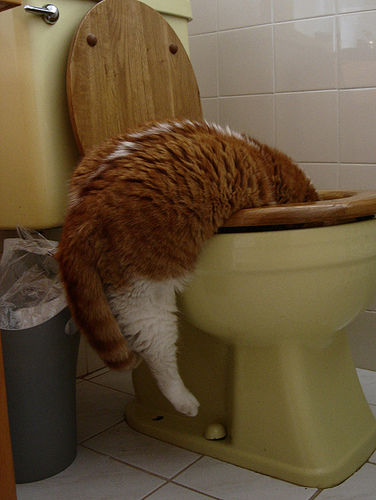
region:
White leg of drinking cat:
[123, 291, 203, 420]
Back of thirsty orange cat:
[153, 151, 234, 191]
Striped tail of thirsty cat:
[58, 242, 143, 387]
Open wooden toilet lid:
[61, 0, 212, 118]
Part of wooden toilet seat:
[261, 203, 330, 234]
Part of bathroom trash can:
[1, 238, 68, 414]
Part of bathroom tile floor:
[103, 451, 173, 492]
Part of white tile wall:
[234, 17, 323, 79]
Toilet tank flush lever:
[21, 1, 60, 26]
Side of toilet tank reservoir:
[5, 43, 50, 145]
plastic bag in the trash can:
[6, 236, 66, 333]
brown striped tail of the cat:
[62, 232, 143, 388]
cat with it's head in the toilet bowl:
[70, 140, 340, 377]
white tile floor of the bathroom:
[87, 435, 179, 496]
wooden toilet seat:
[270, 196, 373, 229]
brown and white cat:
[78, 150, 336, 420]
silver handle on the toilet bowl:
[21, 3, 67, 39]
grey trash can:
[6, 337, 87, 490]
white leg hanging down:
[102, 262, 212, 449]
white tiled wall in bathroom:
[219, 13, 358, 130]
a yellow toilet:
[1, 3, 368, 486]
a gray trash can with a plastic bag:
[3, 244, 79, 484]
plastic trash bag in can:
[0, 234, 69, 328]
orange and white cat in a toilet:
[66, 122, 320, 421]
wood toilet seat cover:
[70, 2, 202, 156]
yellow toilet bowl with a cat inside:
[64, 127, 372, 485]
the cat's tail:
[59, 211, 134, 369]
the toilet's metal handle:
[23, 1, 59, 23]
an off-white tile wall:
[197, 4, 373, 370]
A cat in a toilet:
[55, 6, 374, 487]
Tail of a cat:
[50, 228, 143, 376]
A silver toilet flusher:
[21, 0, 63, 30]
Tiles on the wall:
[187, 1, 372, 371]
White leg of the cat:
[140, 333, 203, 421]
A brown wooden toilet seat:
[60, 1, 372, 233]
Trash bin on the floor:
[1, 231, 101, 487]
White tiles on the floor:
[14, 362, 373, 497]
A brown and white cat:
[53, 110, 321, 422]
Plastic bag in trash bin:
[0, 228, 89, 487]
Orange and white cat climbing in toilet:
[51, 118, 320, 415]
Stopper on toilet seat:
[84, 30, 92, 40]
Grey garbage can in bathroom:
[0, 222, 76, 479]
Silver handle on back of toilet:
[21, 0, 53, 20]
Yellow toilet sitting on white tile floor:
[0, 0, 370, 485]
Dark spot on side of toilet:
[149, 410, 159, 419]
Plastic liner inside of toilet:
[0, 222, 69, 325]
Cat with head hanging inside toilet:
[53, 114, 335, 410]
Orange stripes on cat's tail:
[63, 274, 134, 368]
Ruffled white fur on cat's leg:
[110, 281, 183, 385]